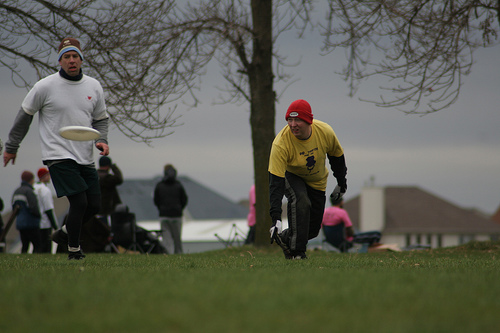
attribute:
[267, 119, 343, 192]
shirt — yellow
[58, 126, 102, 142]
frisbee — white, flying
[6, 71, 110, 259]
man — here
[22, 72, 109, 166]
shirt — white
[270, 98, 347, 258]
man — here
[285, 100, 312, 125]
cap — here, worn, for warmth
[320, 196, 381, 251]
person — here, sitting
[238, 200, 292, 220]
mountain — distant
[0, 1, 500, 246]
tree — here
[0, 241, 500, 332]
field — here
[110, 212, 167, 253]
chair — black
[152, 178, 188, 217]
jacket — black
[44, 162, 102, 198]
shorts — here